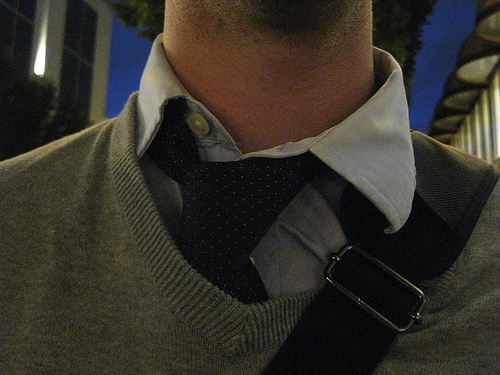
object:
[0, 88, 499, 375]
sweater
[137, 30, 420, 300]
shirt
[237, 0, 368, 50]
shadow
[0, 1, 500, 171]
building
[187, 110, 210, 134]
button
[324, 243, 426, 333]
buckle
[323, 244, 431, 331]
attachment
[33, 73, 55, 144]
bush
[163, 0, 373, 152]
neck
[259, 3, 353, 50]
stubble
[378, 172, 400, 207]
ground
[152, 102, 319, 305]
pattern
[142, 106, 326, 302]
neck tie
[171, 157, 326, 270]
knot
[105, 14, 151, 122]
sky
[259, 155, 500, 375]
strap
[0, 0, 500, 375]
male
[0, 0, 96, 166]
window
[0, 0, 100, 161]
frame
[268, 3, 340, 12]
chin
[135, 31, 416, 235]
collar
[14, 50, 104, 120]
four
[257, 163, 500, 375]
bag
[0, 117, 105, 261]
shoulder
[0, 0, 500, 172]
background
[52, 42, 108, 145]
five